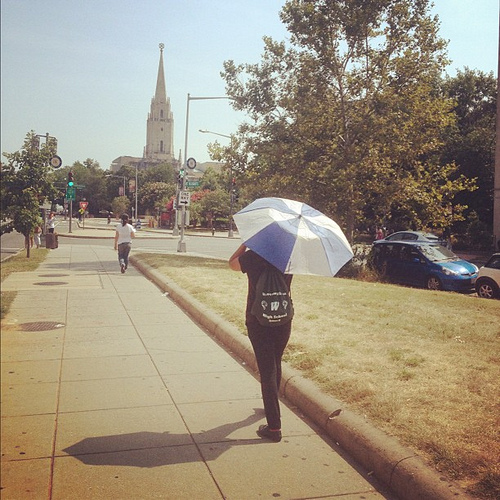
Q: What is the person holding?
A: Umbrella.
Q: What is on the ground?
A: Shadow.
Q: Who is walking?
A: People.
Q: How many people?
A: 2.